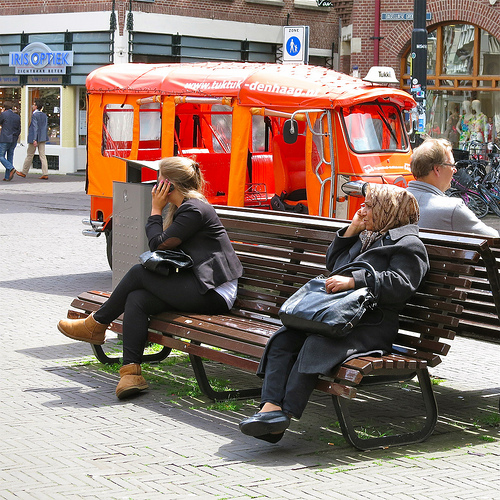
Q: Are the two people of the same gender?
A: Yes, all the people are female.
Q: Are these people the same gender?
A: Yes, all the people are female.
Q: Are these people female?
A: Yes, all the people are female.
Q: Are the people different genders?
A: No, all the people are female.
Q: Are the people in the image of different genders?
A: No, all the people are female.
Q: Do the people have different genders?
A: No, all the people are female.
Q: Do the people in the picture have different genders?
A: No, all the people are female.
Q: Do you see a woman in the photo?
A: Yes, there is a woman.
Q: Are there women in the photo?
A: Yes, there is a woman.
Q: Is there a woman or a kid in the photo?
A: Yes, there is a woman.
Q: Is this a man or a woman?
A: This is a woman.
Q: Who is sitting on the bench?
A: The woman is sitting on the bench.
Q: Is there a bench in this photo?
A: Yes, there is a bench.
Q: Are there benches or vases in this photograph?
A: Yes, there is a bench.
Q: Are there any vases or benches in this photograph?
A: Yes, there is a bench.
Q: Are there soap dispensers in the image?
A: No, there are no soap dispensers.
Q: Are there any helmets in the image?
A: No, there are no helmets.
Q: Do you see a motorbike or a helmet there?
A: No, there are no helmets or motorcycles.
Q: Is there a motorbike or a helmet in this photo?
A: No, there are no helmets or motorcycles.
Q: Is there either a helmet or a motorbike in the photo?
A: No, there are no helmets or motorcycles.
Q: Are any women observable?
A: Yes, there is a woman.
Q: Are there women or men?
A: Yes, there is a woman.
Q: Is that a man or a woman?
A: That is a woman.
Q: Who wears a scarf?
A: The woman wears a scarf.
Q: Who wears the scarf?
A: The woman wears a scarf.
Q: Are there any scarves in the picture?
A: Yes, there is a scarf.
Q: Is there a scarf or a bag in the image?
A: Yes, there is a scarf.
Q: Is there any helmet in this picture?
A: No, there are no helmets.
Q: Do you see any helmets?
A: No, there are no helmets.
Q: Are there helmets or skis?
A: No, there are no helmets or skis.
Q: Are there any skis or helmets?
A: No, there are no helmets or skis.